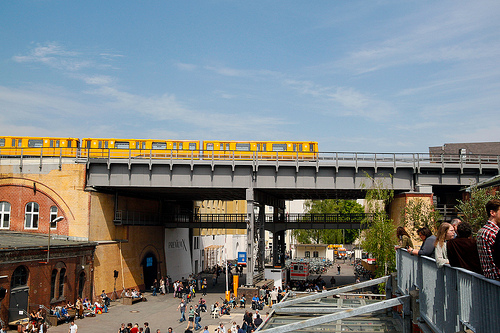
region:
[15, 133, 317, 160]
yellow passenger train on bridge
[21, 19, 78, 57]
white clouds in blue sky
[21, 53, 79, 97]
white clouds in blue sky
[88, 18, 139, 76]
white clouds in blue sky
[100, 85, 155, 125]
white clouds in blue sky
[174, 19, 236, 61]
white clouds in blue sky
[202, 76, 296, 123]
white clouds in blue sky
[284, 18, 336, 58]
white clouds in blue sky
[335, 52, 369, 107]
white clouds in blue sky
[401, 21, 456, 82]
white clouds in blue sky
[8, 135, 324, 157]
yellow train on bridge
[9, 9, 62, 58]
white clouds in blue sky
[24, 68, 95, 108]
white clouds in blue sky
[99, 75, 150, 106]
white clouds in blue sky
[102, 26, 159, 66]
white clouds in blue sky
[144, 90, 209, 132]
white clouds in blue sky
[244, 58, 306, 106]
white clouds in blue sky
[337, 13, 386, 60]
white clouds in blue sky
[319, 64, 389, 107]
white clouds in blue sky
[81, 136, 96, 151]
Small yellow window on train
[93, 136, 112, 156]
Small yellow window on train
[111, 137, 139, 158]
Small yellow window on train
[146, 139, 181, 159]
Small yellow window on train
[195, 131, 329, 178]
Ywllow train cart on bridge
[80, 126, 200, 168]
Yellow train cart on bridge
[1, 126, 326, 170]
Yellow train cart on bridge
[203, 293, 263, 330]
People walking on the pavement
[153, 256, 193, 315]
People walking on the pavement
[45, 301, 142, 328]
People walking on the pavement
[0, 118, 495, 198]
Bright Yellow Train Moving on Bridge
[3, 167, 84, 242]
Arch Seprating the light brick and dark brick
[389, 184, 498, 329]
People looking over onto the street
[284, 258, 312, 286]
Ambulance driving down the street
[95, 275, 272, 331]
People standing in the street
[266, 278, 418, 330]
Grey Metal supporting beams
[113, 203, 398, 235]
Metal Walkway between the buildings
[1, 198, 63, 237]
Broken Windows on the second floor of building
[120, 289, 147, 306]
Two people sitting on a couch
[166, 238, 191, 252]
Writing tagged on a white wall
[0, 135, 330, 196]
yellow passenger train crossing bridge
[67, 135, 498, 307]
gray concrete bridge with train crossing it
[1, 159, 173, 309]
tan and brown building in run down neighborhood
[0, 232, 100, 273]
dark tar roof on top of brown building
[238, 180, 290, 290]
concrete support beams to overhead train bridge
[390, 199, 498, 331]
people standing next to green metal fence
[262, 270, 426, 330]
concrete support beam reinforcing fence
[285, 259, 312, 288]
back side of ambulance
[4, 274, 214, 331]
crowd of people sitting along street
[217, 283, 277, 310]
first responders standing on street